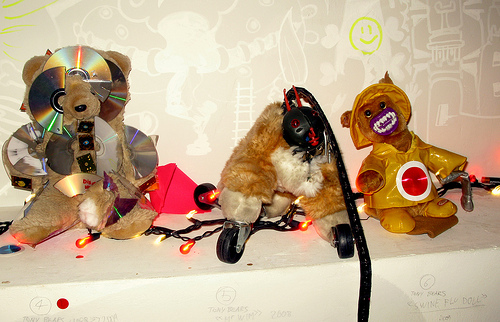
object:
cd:
[43, 45, 117, 102]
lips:
[378, 119, 401, 137]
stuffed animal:
[215, 97, 355, 240]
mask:
[290, 117, 301, 128]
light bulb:
[192, 183, 221, 205]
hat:
[340, 69, 415, 151]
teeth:
[389, 123, 395, 126]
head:
[358, 92, 407, 140]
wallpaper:
[434, 1, 491, 130]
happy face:
[347, 8, 391, 64]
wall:
[7, 11, 499, 178]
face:
[358, 93, 406, 141]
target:
[400, 159, 429, 196]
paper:
[150, 156, 211, 220]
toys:
[0, 39, 163, 253]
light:
[295, 213, 324, 236]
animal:
[340, 66, 476, 239]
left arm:
[421, 138, 460, 179]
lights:
[73, 229, 95, 250]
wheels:
[214, 225, 250, 265]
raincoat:
[350, 139, 467, 208]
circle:
[393, 159, 435, 202]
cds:
[25, 61, 101, 134]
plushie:
[214, 97, 351, 241]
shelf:
[22, 257, 493, 308]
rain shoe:
[378, 209, 417, 235]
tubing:
[309, 101, 379, 322]